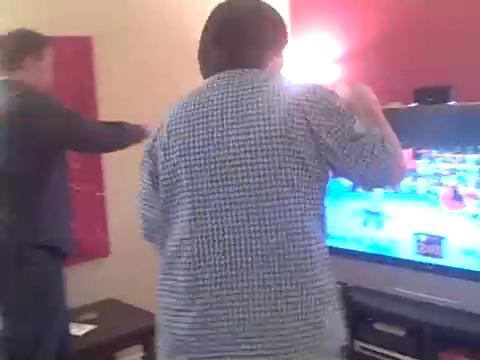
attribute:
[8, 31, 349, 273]
people — standing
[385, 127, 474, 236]
screen — on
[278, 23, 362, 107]
light — blurred, bright, on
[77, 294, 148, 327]
table — low, dark, brown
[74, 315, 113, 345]
paper — white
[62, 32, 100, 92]
picture — hanging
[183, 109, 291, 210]
shirt — long sleeved, white, black, checkered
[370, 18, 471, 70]
wall — white, red, pink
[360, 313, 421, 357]
box — black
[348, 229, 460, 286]
tv — large, grey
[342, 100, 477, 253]
television — next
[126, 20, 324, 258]
man — towards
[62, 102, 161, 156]
arm — out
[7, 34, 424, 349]
men — standing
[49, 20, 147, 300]
artwork — red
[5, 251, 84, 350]
pants — black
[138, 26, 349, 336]
person — wearing